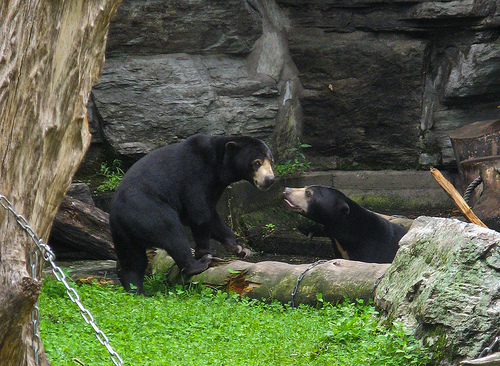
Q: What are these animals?
A: Two grown bears.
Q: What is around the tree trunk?
A: A chain.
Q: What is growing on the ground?
A: Bright green foliage.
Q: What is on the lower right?
A: Large boulder with green moss.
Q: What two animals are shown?
A: Bears.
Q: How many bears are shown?
A: Two.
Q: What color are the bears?
A: Black.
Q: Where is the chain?
A: Around the tree trunk.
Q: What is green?
A: Groundcover.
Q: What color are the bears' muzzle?
A: Brown.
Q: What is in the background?
A: Large wall of stone.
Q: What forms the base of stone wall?
A: Concrete.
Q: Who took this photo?
A: A visitor at the zoo.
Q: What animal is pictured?
A: Black bears.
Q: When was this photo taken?
A: During the afternoon.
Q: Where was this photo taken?
A: At the black bear exhibit at the zoo.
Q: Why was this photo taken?
A: To show the bears interacting.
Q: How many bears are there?
A: There are 2.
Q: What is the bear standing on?
A: A tree trunk.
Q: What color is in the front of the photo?
A: Green.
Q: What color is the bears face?
A: They are beige.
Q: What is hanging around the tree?
A: A chain.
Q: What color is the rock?
A: Grey.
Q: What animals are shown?
A: Bears.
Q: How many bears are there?
A: Two.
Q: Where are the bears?
A: In a zoo.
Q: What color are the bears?
A: Black.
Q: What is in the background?
A: Rocks and logs.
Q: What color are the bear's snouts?
A: Brown.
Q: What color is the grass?
A: Green.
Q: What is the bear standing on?
A: A fallen tree.